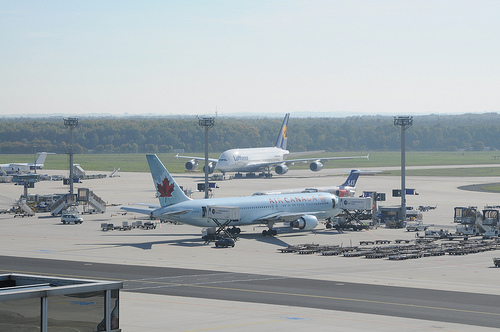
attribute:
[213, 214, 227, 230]
ramp — white, grey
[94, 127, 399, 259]
airplane — grey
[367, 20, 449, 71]
sky — gray , pale 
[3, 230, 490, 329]
tarmac — grey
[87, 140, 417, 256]
plane — white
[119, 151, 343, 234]
airplane — grey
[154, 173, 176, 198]
maple leaf — red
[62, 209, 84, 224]
van — white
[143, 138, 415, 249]
an airplane — grey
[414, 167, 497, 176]
grass — green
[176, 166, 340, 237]
airplane — grey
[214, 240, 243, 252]
car — Black 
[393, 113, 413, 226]
pole — grey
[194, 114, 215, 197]
pole — grey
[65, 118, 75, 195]
pole — grey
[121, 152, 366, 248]
plane — white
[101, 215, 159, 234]
carts — luggage cart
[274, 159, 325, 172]
engines — grey color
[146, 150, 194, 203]
tail wing — white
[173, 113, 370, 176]
airplane — large